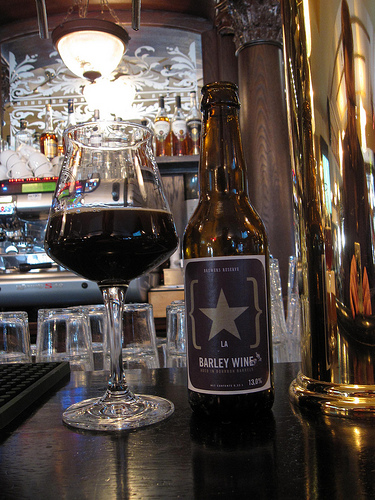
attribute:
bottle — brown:
[160, 89, 283, 426]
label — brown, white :
[183, 252, 271, 395]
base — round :
[63, 390, 173, 432]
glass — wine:
[44, 124, 174, 429]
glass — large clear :
[6, 113, 196, 438]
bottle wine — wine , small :
[167, 247, 292, 373]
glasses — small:
[0, 254, 305, 365]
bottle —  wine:
[186, 80, 274, 410]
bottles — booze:
[13, 89, 203, 157]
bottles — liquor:
[160, 96, 190, 154]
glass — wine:
[54, 124, 175, 436]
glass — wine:
[174, 172, 288, 312]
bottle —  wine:
[280, 449, 318, 465]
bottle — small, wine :
[187, 93, 281, 426]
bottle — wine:
[159, 76, 291, 446]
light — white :
[54, 24, 137, 133]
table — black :
[129, 444, 261, 487]